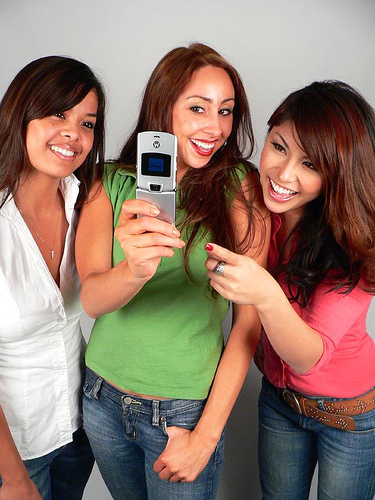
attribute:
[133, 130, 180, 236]
flip phone — silver, open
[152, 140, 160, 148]
button — round, silver, metal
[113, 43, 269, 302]
hair — long, dark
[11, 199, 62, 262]
necklace — silver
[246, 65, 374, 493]
girl — smiling, brown-haired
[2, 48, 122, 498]
girl — smiling, brown-haired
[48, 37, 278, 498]
girl — smiling, brown-haired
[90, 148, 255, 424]
shirt — green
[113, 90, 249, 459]
t-shirt — green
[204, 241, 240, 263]
finger — pointing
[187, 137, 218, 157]
lipstick — red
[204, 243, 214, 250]
polish — red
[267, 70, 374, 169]
hair — dark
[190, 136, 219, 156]
smile — bright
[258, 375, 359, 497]
jeans — blue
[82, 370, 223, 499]
jeans — blue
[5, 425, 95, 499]
jeans — blue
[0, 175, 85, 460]
blouse — white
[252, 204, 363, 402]
shirt — pink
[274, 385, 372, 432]
belt — brown